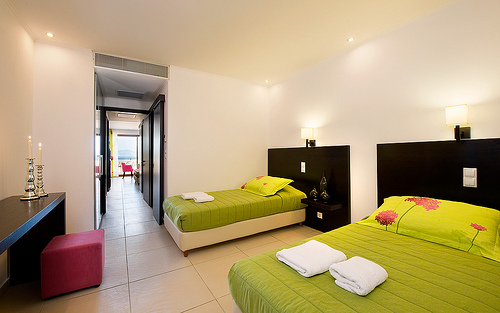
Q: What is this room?
A: A bedroom.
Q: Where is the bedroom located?
A: In a hotel.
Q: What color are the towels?
A: White.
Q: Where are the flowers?
A: On the pillowcases.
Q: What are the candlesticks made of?
A: Silver.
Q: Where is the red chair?
A: Down the hall.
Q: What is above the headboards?
A: Lights.